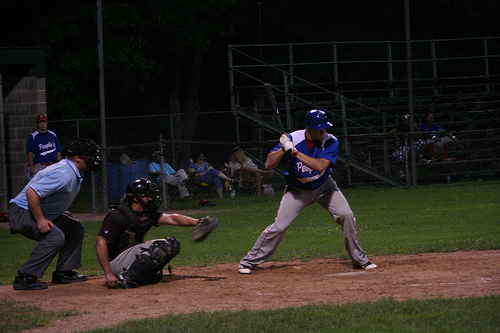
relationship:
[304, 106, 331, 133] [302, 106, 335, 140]
helmet on head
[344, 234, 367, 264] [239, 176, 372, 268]
wrinkles on pants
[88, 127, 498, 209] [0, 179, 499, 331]
fence by field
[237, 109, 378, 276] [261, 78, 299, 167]
man holding bat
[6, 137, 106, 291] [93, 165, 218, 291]
man behind catcher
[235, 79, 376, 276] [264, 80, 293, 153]
batter holding bat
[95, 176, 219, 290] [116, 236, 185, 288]
man wears safety gear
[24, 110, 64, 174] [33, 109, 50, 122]
man wears hat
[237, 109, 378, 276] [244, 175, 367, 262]
man wears pants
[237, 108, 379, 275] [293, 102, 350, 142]
batter wearing helmet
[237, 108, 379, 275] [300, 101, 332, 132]
batter wearing a helmet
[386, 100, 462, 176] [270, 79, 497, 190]
fans sitting in stands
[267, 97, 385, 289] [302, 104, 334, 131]
man wearing helmet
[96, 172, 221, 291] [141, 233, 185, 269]
man wearing knee pads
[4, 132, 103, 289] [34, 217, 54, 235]
man has a hand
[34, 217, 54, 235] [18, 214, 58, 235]
hand on thigh